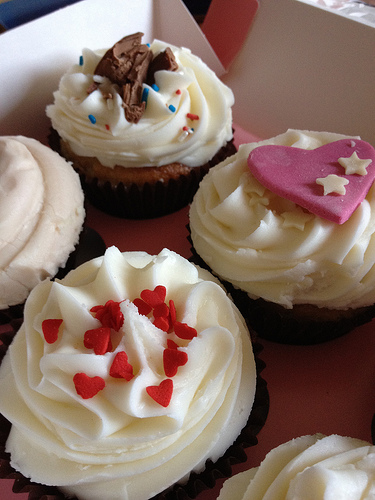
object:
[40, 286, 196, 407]
red hearts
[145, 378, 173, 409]
sprinkle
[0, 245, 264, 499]
cupcake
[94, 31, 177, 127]
chocolate frosting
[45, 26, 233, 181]
vanilla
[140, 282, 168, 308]
red topping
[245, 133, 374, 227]
heart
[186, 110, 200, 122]
red topping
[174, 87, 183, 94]
red topping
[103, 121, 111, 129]
red topping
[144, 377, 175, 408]
red topping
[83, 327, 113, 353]
red topping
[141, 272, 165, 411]
red topping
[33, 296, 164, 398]
red topping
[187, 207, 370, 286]
icing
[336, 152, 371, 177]
star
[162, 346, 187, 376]
heart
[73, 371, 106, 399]
heart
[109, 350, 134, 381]
heart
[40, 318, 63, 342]
heart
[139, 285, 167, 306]
heart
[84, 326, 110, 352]
topping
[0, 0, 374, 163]
box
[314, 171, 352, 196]
star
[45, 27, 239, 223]
cupcake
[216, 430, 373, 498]
cupcake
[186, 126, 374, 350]
cupcake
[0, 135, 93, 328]
cupcake